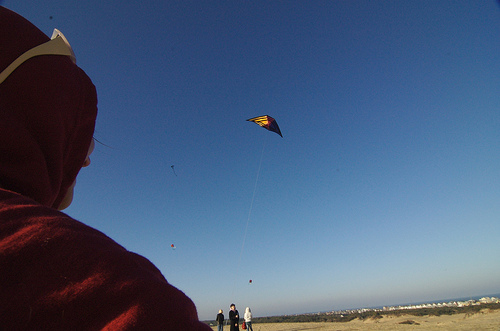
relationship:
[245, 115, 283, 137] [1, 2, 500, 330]
kite in air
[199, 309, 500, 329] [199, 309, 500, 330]
beach has beach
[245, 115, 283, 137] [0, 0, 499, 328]
kite in sky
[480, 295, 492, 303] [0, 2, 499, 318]
building in back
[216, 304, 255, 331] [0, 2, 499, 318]
people are in back